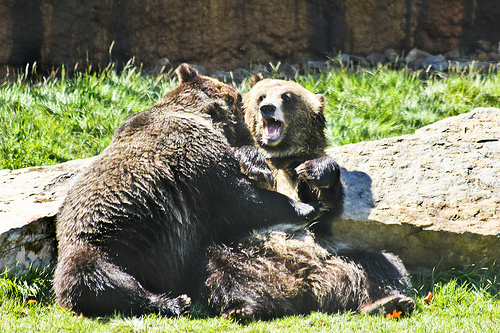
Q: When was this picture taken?
A: During the day.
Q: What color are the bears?
A: Brown.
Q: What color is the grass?
A: Green.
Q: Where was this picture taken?
A: At a zoo.